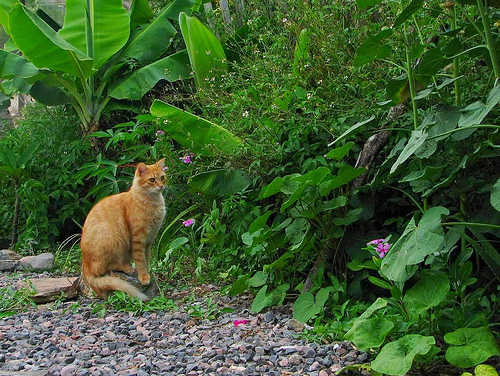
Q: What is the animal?
A: Cat.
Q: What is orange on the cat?
A: Fur.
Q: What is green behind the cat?
A: Leaves.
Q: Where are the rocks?
A: Ground.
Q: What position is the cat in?
A: Sitting.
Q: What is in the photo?
A: A cat.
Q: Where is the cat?
A: Outside somewhere.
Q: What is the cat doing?
A: Sitting.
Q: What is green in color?
A: The leaves.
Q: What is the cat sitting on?
A: A large rock.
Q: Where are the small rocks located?
A: On the ground.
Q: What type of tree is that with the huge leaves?
A: A banana tree.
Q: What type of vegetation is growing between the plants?
A: Weeds.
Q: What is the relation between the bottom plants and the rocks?
A: The plants are touching the rocks.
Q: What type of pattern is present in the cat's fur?
A: Orange stripes.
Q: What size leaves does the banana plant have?
A: Very large leaves.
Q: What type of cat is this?
A: An orange tabby.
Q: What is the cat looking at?
A: The plants.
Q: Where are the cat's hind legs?
A: Curled under his body.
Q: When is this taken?
A: Daytime.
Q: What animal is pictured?
A: A cat.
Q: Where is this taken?
A: In nature.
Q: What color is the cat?
A: Orange.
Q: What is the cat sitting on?
A: Gravel.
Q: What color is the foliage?
A: Green.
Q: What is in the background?
A: Foliage.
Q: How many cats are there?
A: One.